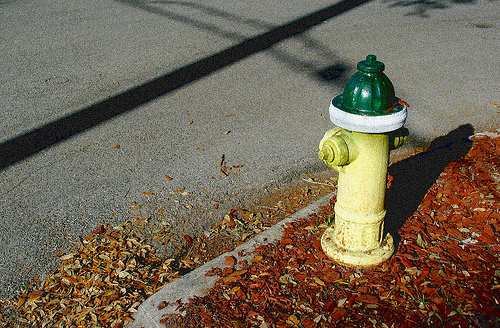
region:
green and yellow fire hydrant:
[310, 48, 414, 261]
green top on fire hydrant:
[345, 54, 397, 110]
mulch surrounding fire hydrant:
[184, 146, 489, 325]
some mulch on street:
[0, 220, 153, 317]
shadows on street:
[8, 3, 328, 183]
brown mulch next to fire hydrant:
[188, 268, 458, 325]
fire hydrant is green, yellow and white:
[328, 47, 399, 265]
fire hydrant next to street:
[325, 47, 408, 257]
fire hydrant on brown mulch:
[309, 55, 406, 267]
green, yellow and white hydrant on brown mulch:
[320, 54, 415, 263]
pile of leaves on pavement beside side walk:
[35, 205, 155, 325]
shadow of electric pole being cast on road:
[35, 61, 212, 153]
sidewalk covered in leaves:
[235, 265, 401, 325]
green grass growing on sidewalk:
[410, 281, 462, 311]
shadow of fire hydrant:
[397, 123, 484, 224]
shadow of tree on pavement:
[380, 0, 485, 25]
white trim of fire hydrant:
[331, 112, 411, 133]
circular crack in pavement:
[41, 66, 75, 91]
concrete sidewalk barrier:
[179, 271, 209, 296]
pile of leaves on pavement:
[60, 228, 161, 286]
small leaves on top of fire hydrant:
[383, 94, 411, 114]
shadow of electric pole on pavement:
[47, 36, 235, 133]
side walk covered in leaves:
[398, 182, 498, 322]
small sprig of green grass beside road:
[403, 283, 433, 312]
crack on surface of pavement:
[19, 157, 64, 196]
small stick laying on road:
[295, 172, 334, 192]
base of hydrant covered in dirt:
[316, 201, 398, 267]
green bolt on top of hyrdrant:
[358, 53, 384, 65]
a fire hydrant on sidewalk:
[302, 35, 444, 290]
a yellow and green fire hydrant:
[285, 25, 447, 313]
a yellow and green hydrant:
[304, 22, 445, 326]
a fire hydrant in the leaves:
[275, 39, 462, 326]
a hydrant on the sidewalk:
[288, 9, 471, 320]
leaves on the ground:
[22, 138, 321, 326]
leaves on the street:
[55, 162, 232, 324]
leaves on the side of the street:
[73, 189, 393, 326]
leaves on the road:
[42, 200, 289, 325]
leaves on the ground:
[225, 165, 497, 317]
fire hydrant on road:
[294, 55, 402, 287]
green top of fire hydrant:
[336, 52, 407, 130]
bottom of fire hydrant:
[302, 232, 386, 274]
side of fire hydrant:
[318, 136, 349, 165]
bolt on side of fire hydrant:
[314, 147, 331, 157]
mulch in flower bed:
[297, 274, 388, 313]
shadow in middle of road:
[108, 50, 245, 126]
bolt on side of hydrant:
[386, 125, 411, 155]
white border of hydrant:
[363, 114, 403, 136]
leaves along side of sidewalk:
[53, 226, 160, 293]